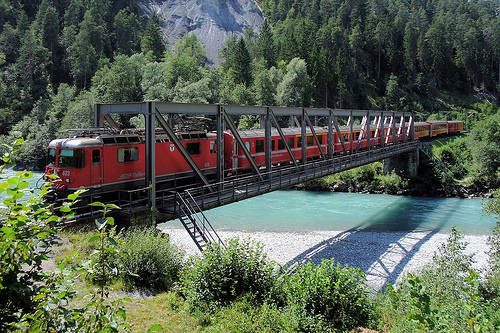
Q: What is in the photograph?
A: A train.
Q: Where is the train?
A: Railroad tracks.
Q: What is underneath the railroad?
A: A river.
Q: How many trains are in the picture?
A: One.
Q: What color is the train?
A: Red.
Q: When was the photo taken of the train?
A: Daytime.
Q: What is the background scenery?
A: Trees.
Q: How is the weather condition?
A: Clear.